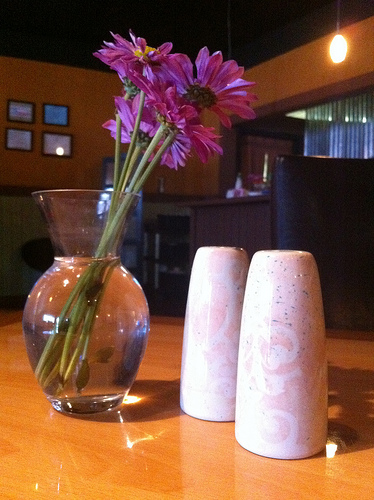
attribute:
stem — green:
[31, 127, 180, 384]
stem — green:
[29, 115, 170, 388]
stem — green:
[47, 82, 145, 396]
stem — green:
[50, 87, 134, 392]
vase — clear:
[20, 181, 154, 419]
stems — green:
[32, 87, 178, 396]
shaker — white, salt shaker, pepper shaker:
[174, 243, 249, 423]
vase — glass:
[22, 195, 133, 345]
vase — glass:
[50, 211, 173, 389]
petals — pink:
[188, 130, 208, 161]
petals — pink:
[207, 99, 230, 129]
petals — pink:
[193, 45, 209, 80]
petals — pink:
[166, 51, 192, 85]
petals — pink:
[215, 97, 253, 119]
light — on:
[324, 32, 354, 67]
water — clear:
[102, 278, 140, 313]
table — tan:
[0, 292, 370, 497]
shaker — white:
[239, 247, 328, 471]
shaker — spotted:
[230, 236, 348, 464]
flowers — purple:
[64, 24, 267, 150]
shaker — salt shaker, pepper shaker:
[233, 248, 328, 460]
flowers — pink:
[89, 27, 259, 172]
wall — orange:
[0, 56, 201, 309]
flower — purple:
[165, 50, 258, 130]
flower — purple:
[100, 28, 174, 81]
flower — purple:
[103, 88, 158, 151]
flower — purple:
[154, 88, 222, 164]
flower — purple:
[150, 111, 191, 172]